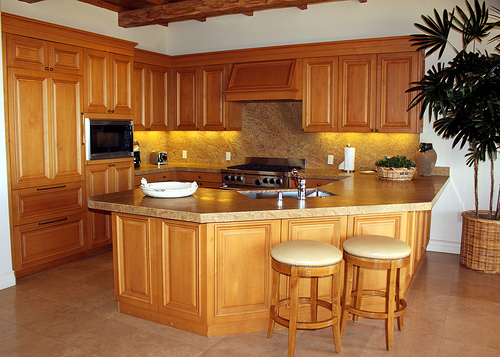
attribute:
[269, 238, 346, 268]
cushions — white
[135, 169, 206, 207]
dish — white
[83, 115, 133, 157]
microwave — stainless steel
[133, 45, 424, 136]
cabinets — finished, wood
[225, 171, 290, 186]
oven — stainless steel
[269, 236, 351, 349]
bar stool — finished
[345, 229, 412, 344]
bar stool — finished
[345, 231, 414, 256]
upholstery — white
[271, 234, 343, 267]
upholstery — white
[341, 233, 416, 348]
bar stool — wooden, light colored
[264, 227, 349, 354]
stool — light colored, wooden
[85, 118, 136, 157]
microwave — built-in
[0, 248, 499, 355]
floor — tiled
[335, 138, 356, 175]
holder — paper towel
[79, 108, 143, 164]
microwave — stainless steel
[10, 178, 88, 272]
drawers — blended, wood, storage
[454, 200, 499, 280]
basket — wicker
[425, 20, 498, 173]
plant — potted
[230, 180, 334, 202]
sink — stainless steel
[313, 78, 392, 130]
cabinets — light colored, wooden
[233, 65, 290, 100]
hood — range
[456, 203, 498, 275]
pot — brown, wicker styled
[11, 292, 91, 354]
floor — tan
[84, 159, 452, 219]
counter — sleek, granite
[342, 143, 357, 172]
roll — paper towel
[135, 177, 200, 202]
bowl — white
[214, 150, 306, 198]
oven — stainless steel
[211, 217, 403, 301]
cabinettes — brown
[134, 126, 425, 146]
lighting — recessed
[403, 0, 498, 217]
plant — green, potted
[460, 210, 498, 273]
basket — wicker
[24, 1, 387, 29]
beams — exposed, wood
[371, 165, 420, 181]
basket — wicker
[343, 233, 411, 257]
cushion — white